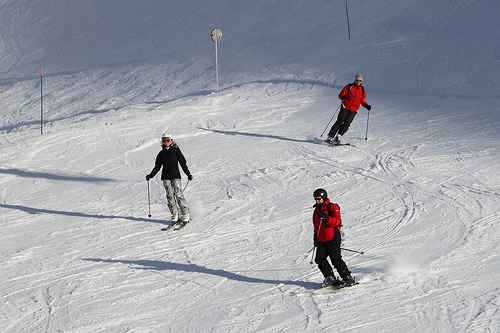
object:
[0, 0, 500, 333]
snow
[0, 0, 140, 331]
hill side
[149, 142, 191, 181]
blackjacket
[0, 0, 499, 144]
hill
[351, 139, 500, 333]
slope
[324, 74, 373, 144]
man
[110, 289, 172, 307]
tracks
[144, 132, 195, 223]
person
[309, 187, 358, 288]
man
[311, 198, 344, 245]
jacket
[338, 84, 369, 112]
jacket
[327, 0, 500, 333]
hill side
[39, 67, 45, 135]
pole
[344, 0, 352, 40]
pole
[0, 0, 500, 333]
ground